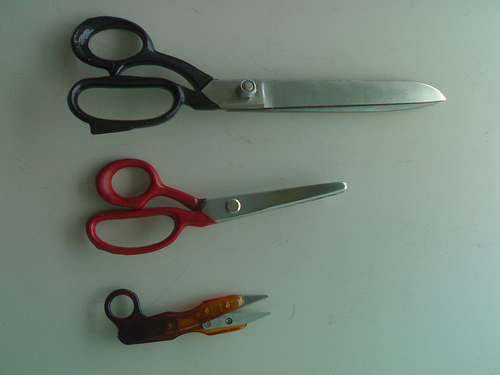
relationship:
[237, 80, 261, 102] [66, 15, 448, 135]
bolts on scissors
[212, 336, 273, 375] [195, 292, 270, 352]
hair by pointed blades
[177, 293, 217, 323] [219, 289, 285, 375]
raised screw on blade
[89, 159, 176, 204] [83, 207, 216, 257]
round hole smaller than oval hole on handled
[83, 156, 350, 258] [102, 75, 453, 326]
scissors on table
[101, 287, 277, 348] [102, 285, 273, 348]
scissors are smallest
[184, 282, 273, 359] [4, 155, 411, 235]
blade on scissors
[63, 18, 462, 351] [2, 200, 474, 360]
scissors lay on a table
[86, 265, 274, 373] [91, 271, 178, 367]
smallest pair has a dark brown handle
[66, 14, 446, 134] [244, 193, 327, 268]
large blades are silver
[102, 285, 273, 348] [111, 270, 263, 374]
smallest pair has its blade ajar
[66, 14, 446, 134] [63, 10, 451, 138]
large are blade scissors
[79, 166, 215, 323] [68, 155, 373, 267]
red handled scissors are common household scissors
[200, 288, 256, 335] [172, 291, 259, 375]
upper half of scissors are orange in color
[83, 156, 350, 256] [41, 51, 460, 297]
scissors lay on a white surface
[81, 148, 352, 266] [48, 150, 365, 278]
medium pair of scissors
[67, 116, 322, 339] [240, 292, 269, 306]
all scissors and blade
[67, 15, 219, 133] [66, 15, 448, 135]
handle of scissors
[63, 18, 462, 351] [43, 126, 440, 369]
scissors on a flat white surface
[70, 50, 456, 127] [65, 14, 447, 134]
large scissor over two smaller scissor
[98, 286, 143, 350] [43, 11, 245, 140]
round and oval opening on scissor handle